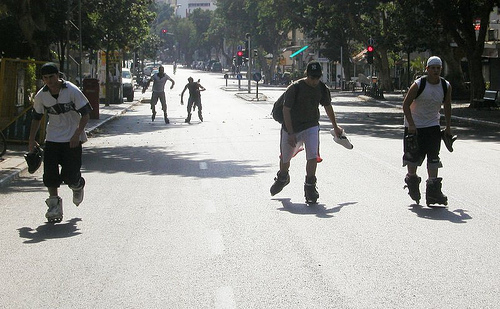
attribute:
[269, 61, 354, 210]
guy — skating, rollerblading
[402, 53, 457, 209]
guy — rollerblading, skating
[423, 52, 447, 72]
hat — white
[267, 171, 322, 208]
rollerblades — black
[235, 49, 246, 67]
light — red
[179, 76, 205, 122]
person — rollerblading, skating, roller blading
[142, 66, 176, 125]
person — rollerblading, skating, roller blading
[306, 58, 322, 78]
hat — black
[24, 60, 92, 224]
man — rollerblading, skating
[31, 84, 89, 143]
shirt — white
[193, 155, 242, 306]
line — white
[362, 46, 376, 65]
light — red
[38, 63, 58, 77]
hat — black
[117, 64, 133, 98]
vehicle — white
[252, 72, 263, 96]
sign — blue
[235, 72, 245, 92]
sign — blue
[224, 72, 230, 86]
sign — blue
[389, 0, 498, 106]
tree — large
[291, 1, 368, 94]
tree — large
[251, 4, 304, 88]
tree — large